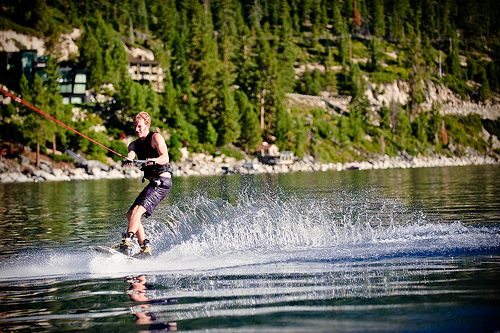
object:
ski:
[88, 245, 144, 265]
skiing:
[0, 88, 174, 264]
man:
[108, 111, 174, 253]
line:
[0, 89, 125, 159]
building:
[0, 49, 88, 107]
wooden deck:
[131, 74, 165, 84]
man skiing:
[88, 111, 173, 263]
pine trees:
[231, 90, 262, 157]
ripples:
[0, 226, 498, 332]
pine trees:
[200, 117, 219, 148]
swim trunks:
[126, 176, 174, 218]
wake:
[0, 162, 499, 333]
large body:
[235, 175, 484, 323]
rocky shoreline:
[0, 158, 498, 185]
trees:
[341, 59, 369, 97]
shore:
[0, 132, 499, 186]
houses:
[281, 92, 382, 128]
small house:
[254, 141, 279, 160]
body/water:
[0, 162, 499, 332]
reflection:
[122, 273, 177, 330]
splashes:
[120, 184, 495, 273]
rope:
[0, 86, 131, 162]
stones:
[8, 170, 21, 180]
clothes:
[127, 131, 173, 178]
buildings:
[124, 60, 167, 96]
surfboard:
[79, 230, 156, 267]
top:
[127, 131, 175, 178]